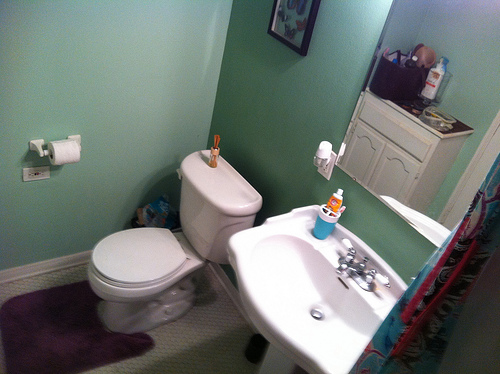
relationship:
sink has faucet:
[223, 203, 423, 372] [338, 236, 360, 263]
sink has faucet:
[223, 203, 423, 372] [366, 266, 390, 293]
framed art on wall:
[267, 0, 326, 54] [207, 0, 455, 290]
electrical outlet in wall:
[23, 165, 51, 181] [0, 1, 233, 281]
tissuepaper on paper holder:
[45, 139, 82, 166] [26, 133, 83, 157]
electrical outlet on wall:
[18, 165, 53, 183] [0, 1, 233, 281]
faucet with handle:
[316, 247, 416, 298] [371, 270, 390, 287]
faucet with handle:
[316, 247, 416, 298] [340, 237, 356, 255]